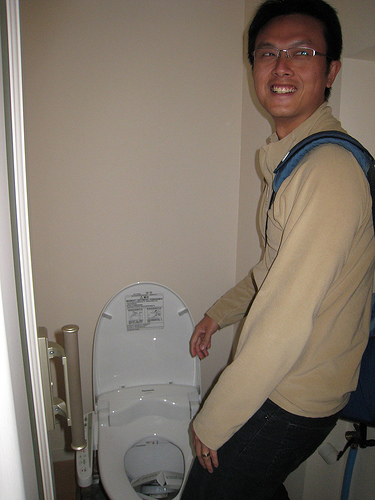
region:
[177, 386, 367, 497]
black pants on a man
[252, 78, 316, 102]
a wide grin from a man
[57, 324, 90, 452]
handle on door of bathroom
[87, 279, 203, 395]
back of toilet seat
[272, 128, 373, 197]
blue strap on man back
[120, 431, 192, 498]
hole in toilet seat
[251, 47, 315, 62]
mans glasses on face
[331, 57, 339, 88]
ear of man standing in bathroom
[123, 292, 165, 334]
label and instructions on toilet seat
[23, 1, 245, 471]
back wall in bathroom behind seat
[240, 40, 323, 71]
man wearing the eyeglasses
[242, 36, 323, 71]
man wearing the eyeglasses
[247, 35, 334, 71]
man wearing the eyeglasses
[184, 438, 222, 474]
man is wearing a ring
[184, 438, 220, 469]
man is wearing a ring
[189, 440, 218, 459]
man is wearing a ring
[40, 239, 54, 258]
Small part of a white wall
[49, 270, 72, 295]
Small part of a white wall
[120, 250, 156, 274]
Small part of a white wall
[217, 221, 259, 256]
Small part of a white wall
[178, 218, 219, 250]
Small part of a white wall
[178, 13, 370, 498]
this is a person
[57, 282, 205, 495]
this is a toilet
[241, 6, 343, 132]
this is a head of a person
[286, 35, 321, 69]
this is an eye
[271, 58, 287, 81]
this is a nose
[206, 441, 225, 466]
the finger on the hand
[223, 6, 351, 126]
head of a person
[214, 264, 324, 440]
arm of a person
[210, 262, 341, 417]
an arm of a person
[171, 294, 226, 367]
hand of a person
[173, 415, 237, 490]
hand of a person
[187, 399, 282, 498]
leg of a person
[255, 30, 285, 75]
eye of a person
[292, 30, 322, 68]
eye of a person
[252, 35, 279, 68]
an eye of a person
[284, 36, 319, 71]
an eye of a person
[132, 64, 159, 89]
the wall is tan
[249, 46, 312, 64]
glasses on the face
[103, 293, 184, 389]
lid of the toilet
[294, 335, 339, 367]
the sweater is tan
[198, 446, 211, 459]
ring on the finger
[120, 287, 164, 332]
label on the toilet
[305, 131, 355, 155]
strap on the shoulder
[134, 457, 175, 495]
bowl of the toilet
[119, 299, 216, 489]
a bathroom toilet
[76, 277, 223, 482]
a bathroom toilet is white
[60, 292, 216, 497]
a bathroom toilet with lid up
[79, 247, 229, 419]
lid up on the toilet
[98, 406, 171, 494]
bathroom seat is down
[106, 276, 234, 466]
a clean bathroom toilet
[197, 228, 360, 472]
a person wearin g ashirt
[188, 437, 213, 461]
a person wearing a ring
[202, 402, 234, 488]
a person with a ring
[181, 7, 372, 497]
a man wearing glasses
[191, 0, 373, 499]
a man wearing jeans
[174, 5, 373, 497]
a man wearing a beige shirt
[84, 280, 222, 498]
a white bathrrom toilet bowl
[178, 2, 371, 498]
a man with dark short hair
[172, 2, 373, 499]
a man with a smile on his face